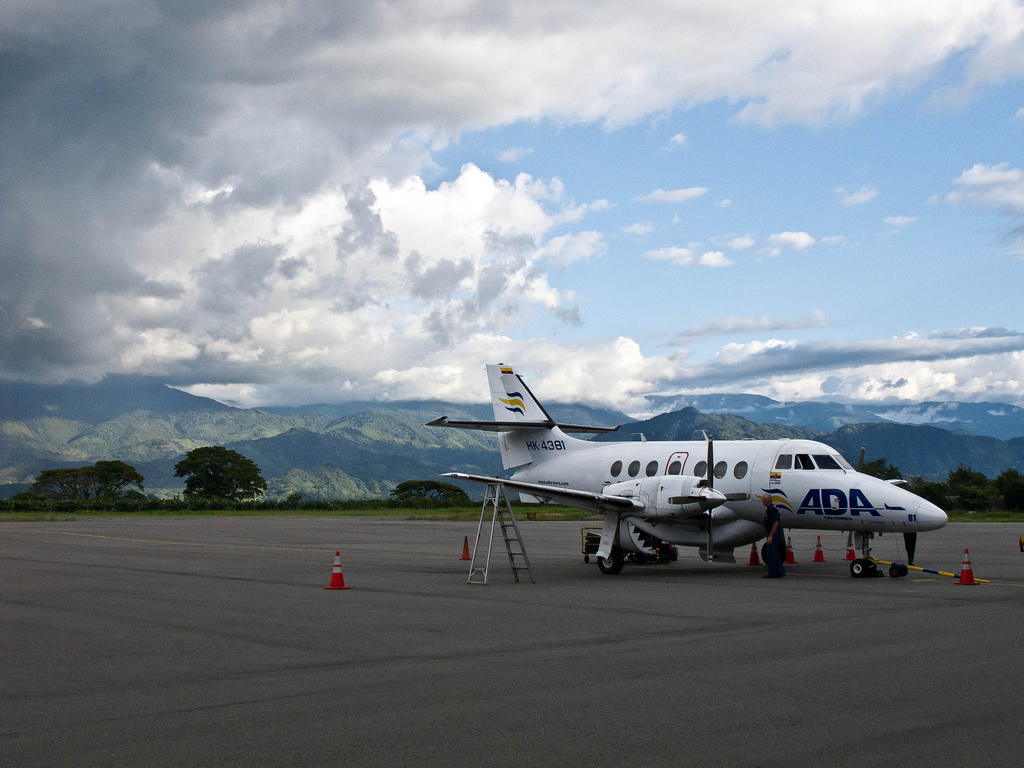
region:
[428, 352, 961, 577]
Plane on the ground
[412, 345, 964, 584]
Plane is on the ground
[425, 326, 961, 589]
Airplane on the ground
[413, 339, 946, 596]
Airplane is on the ground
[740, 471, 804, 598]
Man is in front of a plane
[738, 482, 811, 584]
Man in front of an airplane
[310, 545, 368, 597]
Orange cone on the ground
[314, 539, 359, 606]
Orange cone is on the ground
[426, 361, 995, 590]
White, blue, and yellow airplane.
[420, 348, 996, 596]
Airplane under going maintenance.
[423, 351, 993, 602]
The airplane is parked between cones.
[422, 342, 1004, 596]
A man is checking the airplane.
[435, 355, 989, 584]
A ladder sits under the airplane wing.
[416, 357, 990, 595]
Luggage is being loaded in the underbelly.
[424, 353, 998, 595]
The airplane is being prepared for take off.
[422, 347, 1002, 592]
Mountains are just off the runway.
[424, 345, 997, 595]
The plane has seven windows.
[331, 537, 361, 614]
an orange safety cone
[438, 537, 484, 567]
a small orange safety cone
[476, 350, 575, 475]
tail of the plane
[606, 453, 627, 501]
window on the plane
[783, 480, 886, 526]
logo on the plane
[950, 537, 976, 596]
orange safety cone on ground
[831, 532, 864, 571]
orange safety cone on ground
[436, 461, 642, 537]
side wing on the plane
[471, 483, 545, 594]
ladder to the plane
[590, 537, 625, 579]
wheel on the plane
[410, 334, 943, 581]
Blue and white airplane on the tarmac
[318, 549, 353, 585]
white and orange safety cone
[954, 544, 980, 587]
white and orange safety cone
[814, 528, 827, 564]
white and orange safety cone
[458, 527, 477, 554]
white and orange safety cone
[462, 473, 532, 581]
ladder under the airplane wing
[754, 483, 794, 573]
man standing next to the plane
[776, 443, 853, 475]
windshield on the plane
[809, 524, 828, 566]
white and orange safety cone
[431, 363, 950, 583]
Man standing by plane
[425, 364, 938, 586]
Ladder next to plane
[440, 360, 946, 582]
ADA is on side of plane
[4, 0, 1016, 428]
Sky is very cloudy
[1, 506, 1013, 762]
Orange cones on the ground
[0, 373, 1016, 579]
Mountains are behind plane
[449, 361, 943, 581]
Propeler on the plane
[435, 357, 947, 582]
Wheels on the plane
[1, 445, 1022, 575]
Trees are behind plane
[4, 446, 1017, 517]
Trees have green leaves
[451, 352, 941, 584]
plane on the pavement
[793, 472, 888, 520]
blue letters on the white plane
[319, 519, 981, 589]
orange cones with white stripes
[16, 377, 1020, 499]
mountain range behind the plane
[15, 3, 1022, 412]
cloud covered blue sky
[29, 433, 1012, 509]
trees behind the pavement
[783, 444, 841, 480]
cockpit windows on the plane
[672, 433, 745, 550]
propellor on the plane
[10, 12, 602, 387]
gray clouds in the sky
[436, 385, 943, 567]
a small white plane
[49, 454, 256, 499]
trees behind the plane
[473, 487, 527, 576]
a silver ladder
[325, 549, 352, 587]
an orange cone next to the train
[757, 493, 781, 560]
a person standing by the plane